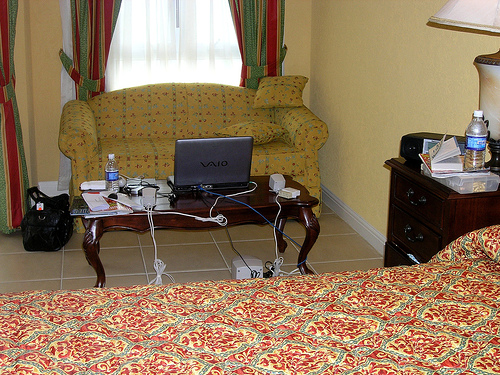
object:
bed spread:
[160, 261, 440, 362]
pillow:
[213, 118, 289, 146]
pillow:
[254, 73, 306, 110]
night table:
[379, 146, 499, 276]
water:
[101, 155, 121, 192]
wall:
[313, 7, 387, 224]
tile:
[6, 209, 391, 276]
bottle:
[461, 107, 489, 172]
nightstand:
[378, 154, 498, 267]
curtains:
[234, 0, 296, 97]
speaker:
[259, 167, 316, 204]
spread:
[1, 224, 498, 374]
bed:
[0, 222, 497, 374]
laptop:
[163, 139, 257, 196]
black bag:
[22, 182, 71, 251]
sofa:
[52, 74, 334, 229]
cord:
[193, 186, 310, 296]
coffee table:
[77, 170, 321, 290]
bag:
[20, 185, 72, 250]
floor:
[0, 202, 382, 292]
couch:
[47, 73, 329, 231]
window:
[101, 0, 246, 94]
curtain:
[1, 1, 34, 234]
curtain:
[57, 1, 123, 96]